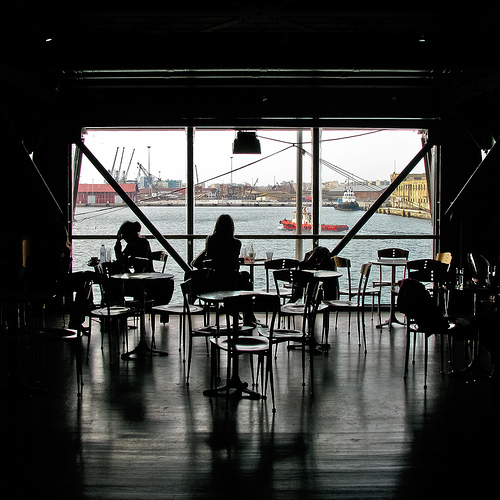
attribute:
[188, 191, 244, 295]
woman — sitting, in the chair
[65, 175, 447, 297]
people — beneath the boats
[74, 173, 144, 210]
building — red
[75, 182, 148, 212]
building — red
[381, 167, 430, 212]
building — red, by the water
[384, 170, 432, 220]
building — tan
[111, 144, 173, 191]
cranes — few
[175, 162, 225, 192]
sky — bright, gray, over seaport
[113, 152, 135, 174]
cranes — behind the red building